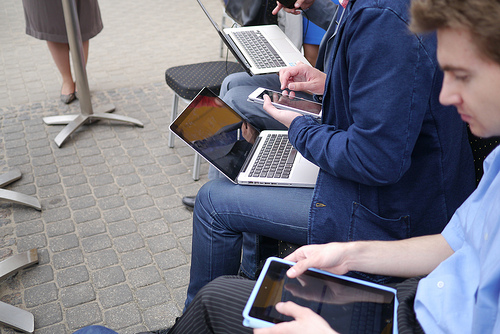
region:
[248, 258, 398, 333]
A computer being held by a human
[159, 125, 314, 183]
A computer being held by a human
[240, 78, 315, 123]
A computer being held by a human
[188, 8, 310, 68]
A computer being held by a human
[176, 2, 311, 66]
A computer being held by a man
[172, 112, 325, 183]
A computer being held by a man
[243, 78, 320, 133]
A computer being held by a man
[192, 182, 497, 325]
A person sitting down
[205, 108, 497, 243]
A person sitting down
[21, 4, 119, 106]
woman standing on the sidewalk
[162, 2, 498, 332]
people sitting down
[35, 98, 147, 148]
base of a podium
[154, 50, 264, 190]
silver and black chair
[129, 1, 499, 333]
man holding a tablet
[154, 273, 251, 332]
thin stripes on the pants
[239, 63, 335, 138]
hand holding a phone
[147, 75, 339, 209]
laptop sitting on the lap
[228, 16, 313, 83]
black keys on a silver keyboard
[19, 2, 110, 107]
woman wearing a skirt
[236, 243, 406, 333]
man playig with a tablet computer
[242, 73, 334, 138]
person holding and using a mini tablet computer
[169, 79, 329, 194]
a mac laptop resting on someone's lap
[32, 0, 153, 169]
legs of a metal table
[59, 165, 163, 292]
concrete pavers make up a sidewalk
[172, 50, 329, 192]
a user using a mini tablet and has laptop resting on lap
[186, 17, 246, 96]
an empty chair on the sidewalk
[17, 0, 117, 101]
a woman standing outside at a table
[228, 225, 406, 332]
man surfing the internet on his tablet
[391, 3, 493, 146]
man staring at his tablet computer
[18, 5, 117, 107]
woman wearing matching shoes and skirt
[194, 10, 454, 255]
man wearing blue coat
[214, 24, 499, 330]
man wearing light blue shirt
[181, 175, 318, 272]
blue jeans of man wearing blue jacket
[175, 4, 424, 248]
two people with laptops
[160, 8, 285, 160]
unoccupied black chair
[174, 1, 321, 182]
two open laptops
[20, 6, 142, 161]
lectern woman is standing behind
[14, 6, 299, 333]
stone walkway people are sitting on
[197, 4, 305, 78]
open laptop beside black chair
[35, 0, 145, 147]
a stand on street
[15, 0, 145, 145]
woman in front a stand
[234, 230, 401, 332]
hands holding a tablet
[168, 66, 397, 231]
a laptop on lap of person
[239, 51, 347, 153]
hands holding a tablet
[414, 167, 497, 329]
a white button on a shirt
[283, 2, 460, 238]
a blue coat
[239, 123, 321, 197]
keyboard is silver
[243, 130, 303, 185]
keys are black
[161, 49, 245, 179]
a chair with black sit